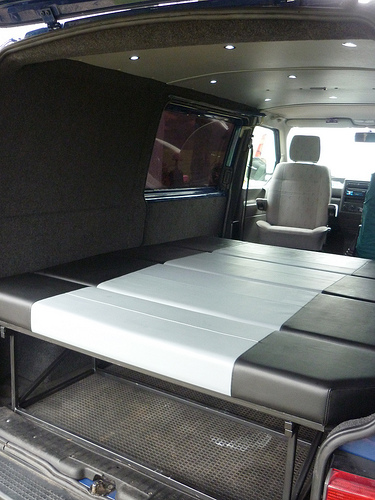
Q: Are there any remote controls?
A: No, there are no remote controls.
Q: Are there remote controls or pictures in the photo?
A: No, there are no remote controls or pictures.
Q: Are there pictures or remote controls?
A: No, there are no remote controls or pictures.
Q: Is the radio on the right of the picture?
A: Yes, the radio is on the right of the image.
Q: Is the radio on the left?
A: No, the radio is on the right of the image.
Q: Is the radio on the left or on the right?
A: The radio is on the right of the image.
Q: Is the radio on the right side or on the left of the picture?
A: The radio is on the right of the image.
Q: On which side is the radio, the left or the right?
A: The radio is on the right of the image.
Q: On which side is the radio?
A: The radio is on the right of the image.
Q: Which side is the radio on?
A: The radio is on the right of the image.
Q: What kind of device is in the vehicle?
A: The device is a radio.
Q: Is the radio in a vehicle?
A: Yes, the radio is in a vehicle.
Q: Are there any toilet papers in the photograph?
A: No, there are no toilet papers.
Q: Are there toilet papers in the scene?
A: No, there are no toilet papers.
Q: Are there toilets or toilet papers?
A: No, there are no toilet papers or toilets.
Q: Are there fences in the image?
A: No, there are no fences.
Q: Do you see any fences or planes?
A: No, there are no fences or planes.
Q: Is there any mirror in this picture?
A: Yes, there is a mirror.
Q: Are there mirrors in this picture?
A: Yes, there is a mirror.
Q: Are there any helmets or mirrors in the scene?
A: Yes, there is a mirror.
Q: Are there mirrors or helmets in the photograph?
A: Yes, there is a mirror.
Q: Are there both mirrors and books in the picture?
A: No, there is a mirror but no books.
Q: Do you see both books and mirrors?
A: No, there is a mirror but no books.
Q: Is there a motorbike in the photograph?
A: No, there are no motorcycles.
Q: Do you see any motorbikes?
A: No, there are no motorbikes.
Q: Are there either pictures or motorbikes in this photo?
A: No, there are no motorbikes or pictures.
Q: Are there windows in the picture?
A: Yes, there is a window.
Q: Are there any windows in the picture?
A: Yes, there is a window.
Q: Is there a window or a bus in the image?
A: Yes, there is a window.